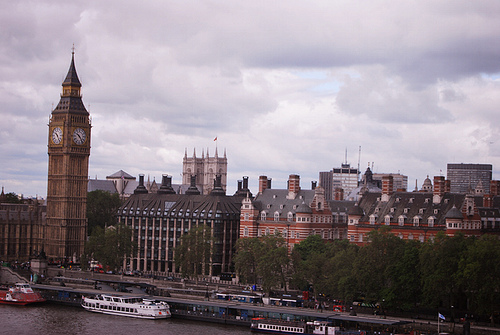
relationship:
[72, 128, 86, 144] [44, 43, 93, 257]
clock on tower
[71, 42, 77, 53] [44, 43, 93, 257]
vane on tower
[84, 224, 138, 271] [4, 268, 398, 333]
tree near bridge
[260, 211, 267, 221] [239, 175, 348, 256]
window on building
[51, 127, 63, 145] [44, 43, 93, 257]
clock on tower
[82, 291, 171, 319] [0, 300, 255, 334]
boat in water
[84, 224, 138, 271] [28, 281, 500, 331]
tree near road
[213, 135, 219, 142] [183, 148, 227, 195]
flag on building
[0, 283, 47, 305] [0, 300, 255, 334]
boat in water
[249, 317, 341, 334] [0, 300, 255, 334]
boat in water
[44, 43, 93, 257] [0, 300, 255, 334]
tower near water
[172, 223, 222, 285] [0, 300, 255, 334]
tree near water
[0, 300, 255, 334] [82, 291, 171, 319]
water holds boat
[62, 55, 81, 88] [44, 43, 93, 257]
top of tower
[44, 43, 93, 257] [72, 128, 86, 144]
tower has clock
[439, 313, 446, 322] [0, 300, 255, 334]
flag near water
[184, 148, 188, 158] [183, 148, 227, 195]
poit on building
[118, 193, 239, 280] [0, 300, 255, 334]
building near water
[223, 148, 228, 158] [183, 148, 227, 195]
point on building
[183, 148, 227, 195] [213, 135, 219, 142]
building has flag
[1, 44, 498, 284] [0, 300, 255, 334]
city near water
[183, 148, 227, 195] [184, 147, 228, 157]
building has towers